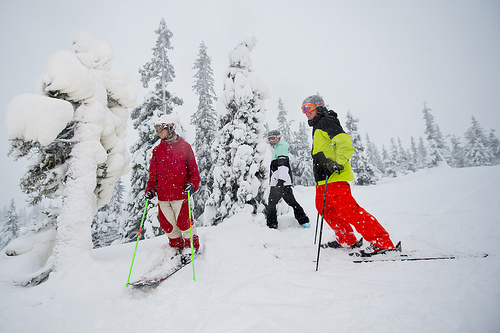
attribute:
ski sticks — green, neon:
[181, 188, 198, 280]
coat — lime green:
[307, 117, 357, 189]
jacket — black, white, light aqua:
[269, 134, 293, 187]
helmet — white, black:
[151, 112, 178, 142]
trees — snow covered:
[111, 44, 371, 192]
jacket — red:
[141, 134, 203, 199]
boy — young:
[137, 110, 206, 261]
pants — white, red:
[150, 202, 202, 257]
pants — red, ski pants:
[311, 182, 394, 249]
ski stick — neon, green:
[184, 187, 196, 281]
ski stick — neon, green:
[124, 197, 147, 292]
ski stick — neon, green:
[184, 188, 201, 288]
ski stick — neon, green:
[118, 190, 149, 285]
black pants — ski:
[261, 183, 311, 228]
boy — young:
[300, 92, 395, 256]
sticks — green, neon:
[127, 185, 197, 280]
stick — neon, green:
[120, 193, 149, 290]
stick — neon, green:
[184, 190, 196, 285]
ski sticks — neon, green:
[126, 187, 203, 293]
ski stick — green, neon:
[123, 194, 150, 284]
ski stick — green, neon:
[183, 188, 198, 275]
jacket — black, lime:
[285, 107, 394, 182]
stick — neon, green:
[123, 200, 152, 286]